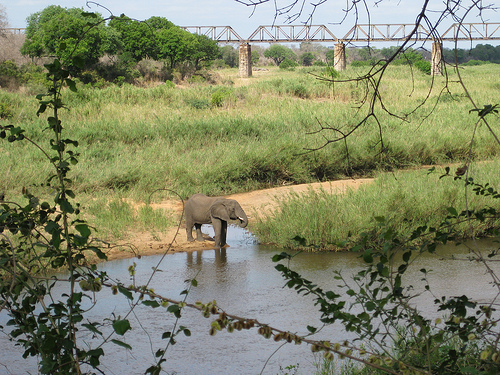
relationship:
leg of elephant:
[177, 222, 202, 242] [182, 187, 250, 251]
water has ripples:
[8, 200, 494, 363] [174, 265, 350, 339]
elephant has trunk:
[183, 191, 247, 245] [238, 212, 250, 231]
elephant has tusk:
[183, 191, 247, 245] [234, 214, 246, 223]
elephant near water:
[182, 193, 248, 248] [13, 240, 485, 350]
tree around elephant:
[19, 4, 222, 81] [182, 193, 248, 248]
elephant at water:
[182, 193, 248, 248] [3, 228, 499, 373]